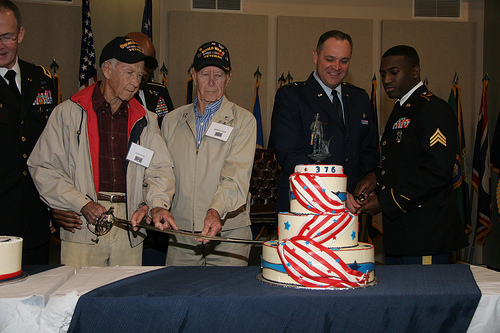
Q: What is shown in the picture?
A: A military celebration.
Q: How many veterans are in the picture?
A: Two.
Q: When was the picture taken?
A: During the celebration.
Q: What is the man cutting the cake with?
A: A saber.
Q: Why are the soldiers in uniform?
A: It's a military celebration.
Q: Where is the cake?
A: On a table.